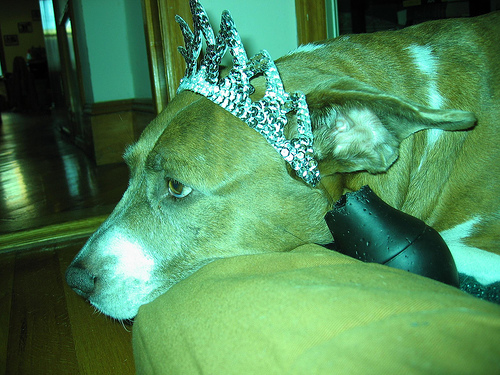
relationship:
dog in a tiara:
[65, 8, 499, 321] [173, 1, 321, 186]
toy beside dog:
[326, 181, 461, 304] [65, 8, 499, 321]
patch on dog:
[409, 42, 449, 175] [65, 8, 499, 321]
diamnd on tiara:
[248, 104, 258, 120] [173, 1, 321, 186]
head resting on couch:
[65, 56, 333, 320] [130, 241, 500, 373]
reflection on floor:
[2, 119, 28, 221] [2, 105, 135, 374]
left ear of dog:
[309, 79, 477, 176] [65, 8, 499, 321]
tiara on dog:
[173, 1, 321, 186] [65, 8, 499, 321]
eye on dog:
[168, 178, 194, 199] [65, 8, 499, 321]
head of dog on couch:
[65, 56, 333, 320] [130, 241, 500, 373]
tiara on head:
[173, 1, 321, 186] [65, 56, 333, 320]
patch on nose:
[99, 226, 158, 319] [65, 267, 94, 299]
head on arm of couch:
[65, 56, 333, 320] [130, 241, 500, 373]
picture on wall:
[3, 33, 18, 47] [1, 2, 43, 74]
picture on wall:
[17, 22, 34, 35] [1, 2, 43, 74]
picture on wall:
[32, 8, 42, 25] [1, 2, 43, 74]